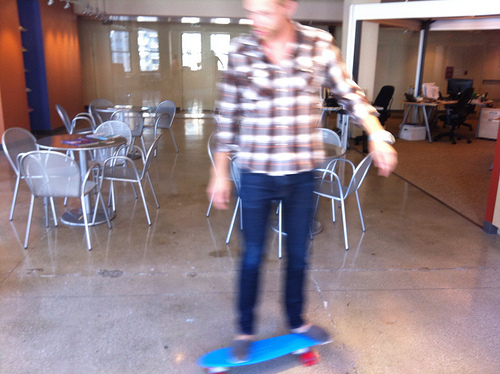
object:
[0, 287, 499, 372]
tile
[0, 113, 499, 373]
floor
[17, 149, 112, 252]
chair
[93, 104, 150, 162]
table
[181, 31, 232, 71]
two windows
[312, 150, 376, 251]
metal chair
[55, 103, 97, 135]
metal chair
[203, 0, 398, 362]
man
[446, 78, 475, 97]
monitor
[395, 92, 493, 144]
desk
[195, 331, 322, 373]
skateboard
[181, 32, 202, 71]
light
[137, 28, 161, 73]
windows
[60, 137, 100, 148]
books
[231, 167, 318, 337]
jeans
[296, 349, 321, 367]
wheel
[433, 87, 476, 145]
office chair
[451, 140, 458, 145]
wheels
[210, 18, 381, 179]
shirt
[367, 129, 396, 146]
watch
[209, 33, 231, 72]
window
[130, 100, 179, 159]
chairs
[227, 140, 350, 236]
table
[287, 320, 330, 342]
feet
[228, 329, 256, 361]
feet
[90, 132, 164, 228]
chair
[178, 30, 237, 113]
door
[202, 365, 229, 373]
wheels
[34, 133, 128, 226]
table